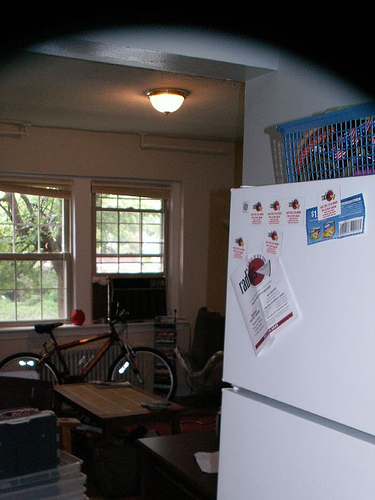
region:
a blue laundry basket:
[270, 105, 370, 180]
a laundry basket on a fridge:
[264, 101, 371, 177]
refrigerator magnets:
[243, 196, 334, 226]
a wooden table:
[65, 378, 167, 423]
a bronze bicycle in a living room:
[8, 309, 167, 389]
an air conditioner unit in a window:
[93, 272, 170, 320]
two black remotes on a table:
[133, 390, 171, 412]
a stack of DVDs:
[148, 315, 181, 400]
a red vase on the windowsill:
[60, 302, 90, 327]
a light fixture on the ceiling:
[139, 76, 205, 123]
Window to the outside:
[1, 180, 74, 325]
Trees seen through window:
[0, 183, 79, 323]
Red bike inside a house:
[4, 307, 186, 402]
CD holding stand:
[148, 307, 183, 408]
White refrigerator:
[212, 182, 374, 497]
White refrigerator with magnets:
[211, 182, 374, 497]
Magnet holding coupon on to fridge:
[302, 184, 373, 248]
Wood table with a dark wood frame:
[46, 371, 194, 440]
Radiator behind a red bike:
[31, 343, 152, 392]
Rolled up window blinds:
[86, 178, 177, 283]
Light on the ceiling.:
[135, 75, 199, 115]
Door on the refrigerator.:
[209, 340, 362, 460]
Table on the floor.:
[51, 346, 197, 417]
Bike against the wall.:
[28, 294, 189, 415]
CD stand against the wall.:
[146, 294, 277, 443]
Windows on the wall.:
[46, 162, 234, 372]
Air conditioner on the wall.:
[74, 250, 187, 328]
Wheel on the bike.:
[14, 350, 75, 407]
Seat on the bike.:
[34, 319, 96, 352]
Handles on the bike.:
[71, 295, 145, 333]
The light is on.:
[146, 84, 189, 116]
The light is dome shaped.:
[145, 82, 195, 125]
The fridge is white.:
[290, 339, 366, 403]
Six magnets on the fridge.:
[243, 192, 354, 266]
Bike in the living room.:
[18, 307, 191, 405]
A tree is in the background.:
[8, 190, 94, 312]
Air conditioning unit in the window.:
[102, 258, 175, 327]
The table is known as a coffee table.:
[62, 376, 182, 442]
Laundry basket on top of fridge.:
[270, 94, 372, 174]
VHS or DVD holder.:
[142, 307, 185, 402]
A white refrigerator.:
[224, 184, 368, 499]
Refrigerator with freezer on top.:
[219, 201, 373, 497]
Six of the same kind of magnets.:
[227, 184, 344, 265]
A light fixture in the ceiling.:
[136, 78, 201, 123]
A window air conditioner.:
[84, 264, 176, 322]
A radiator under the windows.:
[38, 292, 158, 386]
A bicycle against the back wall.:
[4, 309, 184, 402]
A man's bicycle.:
[10, 271, 185, 403]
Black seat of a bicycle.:
[28, 311, 62, 345]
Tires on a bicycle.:
[4, 339, 180, 407]